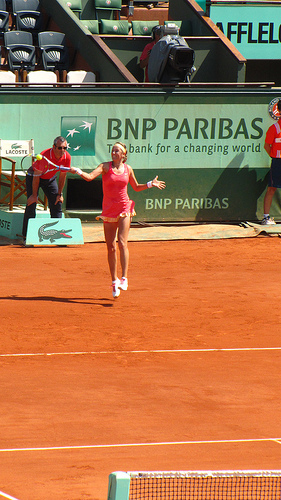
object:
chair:
[37, 31, 74, 63]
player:
[67, 139, 166, 299]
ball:
[35, 153, 42, 162]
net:
[129, 466, 280, 500]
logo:
[59, 104, 274, 170]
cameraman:
[138, 24, 198, 84]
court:
[1, 241, 280, 492]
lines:
[0, 347, 280, 353]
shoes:
[110, 276, 121, 299]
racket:
[19, 153, 80, 179]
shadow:
[0, 291, 114, 310]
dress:
[95, 165, 137, 224]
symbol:
[1, 140, 30, 158]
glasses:
[57, 144, 70, 152]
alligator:
[37, 218, 74, 242]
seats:
[101, 18, 130, 34]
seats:
[39, 30, 68, 68]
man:
[22, 135, 70, 251]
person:
[261, 98, 280, 227]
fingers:
[162, 176, 169, 185]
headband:
[112, 141, 128, 155]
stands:
[0, 1, 275, 88]